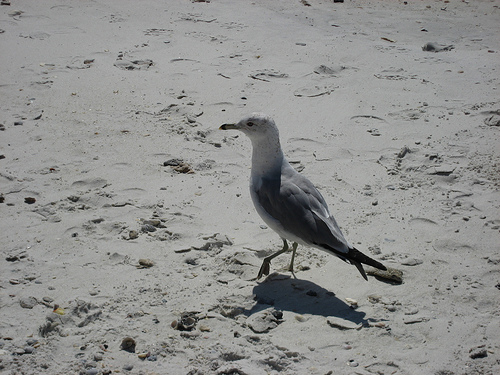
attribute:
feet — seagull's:
[252, 233, 317, 283]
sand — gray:
[1, 1, 498, 372]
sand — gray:
[56, 200, 153, 310]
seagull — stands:
[219, 113, 387, 280]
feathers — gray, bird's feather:
[258, 176, 326, 246]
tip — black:
[219, 121, 234, 133]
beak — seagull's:
[218, 123, 241, 129]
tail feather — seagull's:
[323, 216, 397, 300]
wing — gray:
[248, 173, 411, 296]